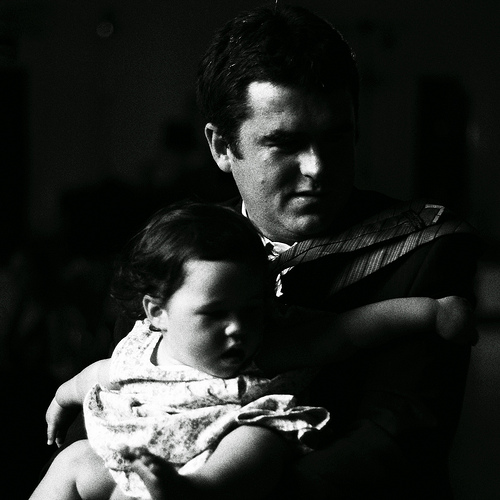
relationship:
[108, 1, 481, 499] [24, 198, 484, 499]
man with child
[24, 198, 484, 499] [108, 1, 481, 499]
child with man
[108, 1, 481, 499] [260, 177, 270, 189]
man has pimple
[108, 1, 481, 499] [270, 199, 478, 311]
man wears tie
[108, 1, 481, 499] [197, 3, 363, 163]
man has hair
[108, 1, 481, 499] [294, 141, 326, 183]
man has nose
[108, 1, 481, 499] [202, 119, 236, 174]
man has ear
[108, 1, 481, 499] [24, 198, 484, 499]
man holding child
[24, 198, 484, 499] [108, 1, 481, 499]
child held by man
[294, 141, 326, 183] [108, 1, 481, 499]
nose on man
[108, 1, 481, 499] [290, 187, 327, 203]
man has mouth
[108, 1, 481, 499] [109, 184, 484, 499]
man wearing jacket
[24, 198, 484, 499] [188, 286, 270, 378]
child has a face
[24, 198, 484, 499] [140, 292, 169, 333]
child has right ear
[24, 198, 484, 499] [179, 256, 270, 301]
child has a forehead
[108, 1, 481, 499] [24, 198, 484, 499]
man holds child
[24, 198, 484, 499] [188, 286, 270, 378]
child has face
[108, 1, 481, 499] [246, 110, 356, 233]
man has face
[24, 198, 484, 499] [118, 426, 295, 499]
child has leg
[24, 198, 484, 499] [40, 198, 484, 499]
child has child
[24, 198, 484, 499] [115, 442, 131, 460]
child has toe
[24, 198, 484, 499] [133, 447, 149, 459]
child has toe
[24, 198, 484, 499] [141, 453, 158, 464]
child has toe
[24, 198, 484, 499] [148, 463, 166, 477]
child has toe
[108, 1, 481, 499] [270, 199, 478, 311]
man has tie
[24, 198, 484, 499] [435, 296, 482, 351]
child has hand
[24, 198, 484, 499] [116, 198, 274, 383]
child has head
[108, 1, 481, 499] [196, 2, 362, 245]
man has head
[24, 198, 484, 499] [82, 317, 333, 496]
child wearing dress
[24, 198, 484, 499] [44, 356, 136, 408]
child has arm